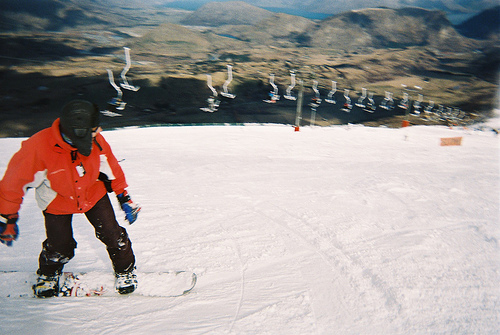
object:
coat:
[0, 116, 129, 222]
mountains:
[294, 5, 461, 51]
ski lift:
[420, 102, 438, 122]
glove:
[117, 190, 144, 225]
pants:
[37, 193, 133, 278]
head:
[57, 97, 103, 147]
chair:
[97, 96, 127, 117]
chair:
[199, 96, 223, 113]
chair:
[281, 90, 297, 103]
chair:
[339, 101, 355, 114]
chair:
[119, 74, 141, 91]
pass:
[72, 163, 88, 177]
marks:
[247, 200, 385, 334]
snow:
[0, 123, 500, 334]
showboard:
[1, 266, 207, 297]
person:
[0, 91, 147, 299]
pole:
[292, 80, 303, 131]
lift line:
[4, 44, 471, 133]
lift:
[410, 98, 428, 116]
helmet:
[59, 95, 103, 136]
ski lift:
[261, 72, 292, 104]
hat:
[57, 97, 100, 143]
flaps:
[68, 125, 97, 157]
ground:
[0, 123, 500, 334]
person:
[266, 80, 276, 97]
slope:
[0, 122, 500, 333]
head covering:
[61, 99, 100, 159]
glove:
[0, 210, 22, 249]